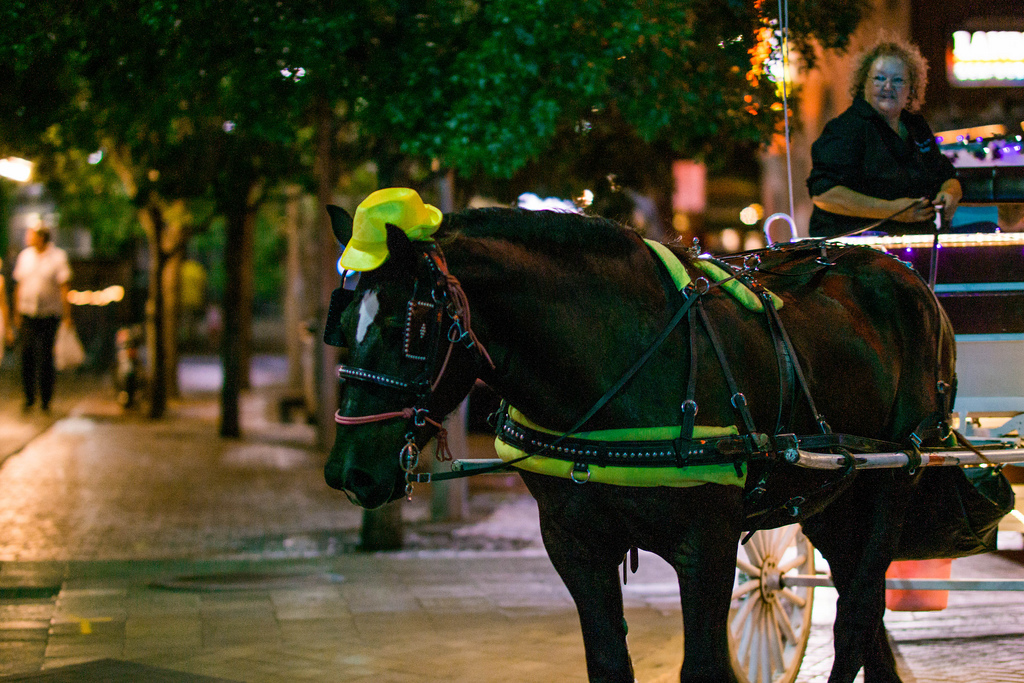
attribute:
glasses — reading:
[869, 59, 913, 90]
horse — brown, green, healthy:
[318, 165, 958, 678]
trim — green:
[633, 217, 787, 326]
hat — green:
[324, 179, 458, 296]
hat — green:
[326, 166, 452, 285]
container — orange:
[877, 543, 975, 621]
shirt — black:
[804, 107, 960, 233]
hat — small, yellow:
[326, 187, 452, 298]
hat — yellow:
[309, 174, 465, 296]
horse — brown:
[276, 163, 1020, 624]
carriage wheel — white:
[661, 485, 878, 669]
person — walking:
[0, 194, 117, 463]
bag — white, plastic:
[30, 293, 132, 419]